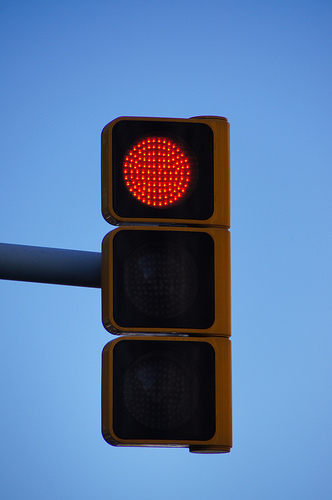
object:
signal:
[99, 116, 231, 452]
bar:
[0, 240, 100, 285]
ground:
[284, 103, 289, 141]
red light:
[125, 133, 191, 207]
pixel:
[130, 169, 133, 172]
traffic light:
[100, 116, 235, 449]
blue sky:
[1, 1, 332, 106]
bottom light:
[111, 338, 218, 444]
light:
[99, 116, 232, 457]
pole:
[0, 241, 101, 289]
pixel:
[140, 137, 149, 144]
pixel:
[184, 170, 190, 174]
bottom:
[100, 332, 231, 450]